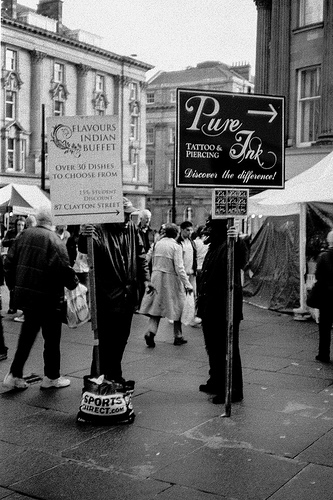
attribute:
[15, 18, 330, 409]
filter — black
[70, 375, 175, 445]
bag — plastic, full, sitting, advertising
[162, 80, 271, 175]
sign — black, written, white, advertising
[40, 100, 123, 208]
sign — white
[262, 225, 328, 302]
buffet — indian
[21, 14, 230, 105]
buildings — large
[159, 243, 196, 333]
coat — white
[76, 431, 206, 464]
tiles — square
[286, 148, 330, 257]
tent — white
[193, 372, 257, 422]
shoes — black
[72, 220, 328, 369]
street — busy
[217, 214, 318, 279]
goods — selling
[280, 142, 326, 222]
canopy — white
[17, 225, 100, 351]
woman — holding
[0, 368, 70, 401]
shoes — white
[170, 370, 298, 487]
pavement — stone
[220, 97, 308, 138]
arrow — white